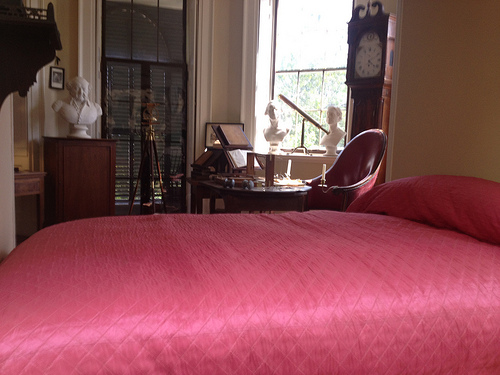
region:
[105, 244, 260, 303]
The blanket on the bed is red.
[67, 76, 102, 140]
The statue is white.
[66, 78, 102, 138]
The statue is a man.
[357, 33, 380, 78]
The clock face is white.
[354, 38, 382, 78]
The clock numbers are black.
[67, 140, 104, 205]
The stand is brown.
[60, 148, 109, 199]
The stand is made from wood.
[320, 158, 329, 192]
The candle is white.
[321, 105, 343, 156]
The statue is white.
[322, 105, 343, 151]
The statue is of a woman.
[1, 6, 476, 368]
Bedroom with furniture and busts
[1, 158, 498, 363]
Made red blanket and pillows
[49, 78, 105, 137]
Armless white plaster bust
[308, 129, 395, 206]
Red concave table chair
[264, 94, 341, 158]
Two white plaster busts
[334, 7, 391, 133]
Brown wooden grandfather clock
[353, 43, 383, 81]
Clock face reading 06:22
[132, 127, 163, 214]
Black and gold tripod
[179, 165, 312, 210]
Brown wooden reading table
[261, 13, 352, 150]
Sun drenched window frame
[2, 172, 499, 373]
hot pink quilted bedspread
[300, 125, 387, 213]
hot pink leather chair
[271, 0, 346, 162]
sun coming in through window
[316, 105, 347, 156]
statue of a man's head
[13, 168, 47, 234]
wooden nightstand with one drawer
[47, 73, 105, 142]
bust of a heavy man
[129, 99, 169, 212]
brown and gold telescope on tripod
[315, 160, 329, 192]
white candle in brass candle holder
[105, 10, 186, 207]
closed blinds on window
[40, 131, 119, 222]
dark stained wooden cabinet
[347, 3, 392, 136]
part of a large grandfather clock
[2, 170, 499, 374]
a large pink bed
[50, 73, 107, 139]
a white sculpture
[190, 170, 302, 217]
part of a brown table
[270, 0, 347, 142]
part of a window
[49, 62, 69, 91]
a small picture frame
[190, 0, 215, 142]
white wall trim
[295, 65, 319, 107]
green tree leaves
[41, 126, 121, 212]
part of a brown cabinet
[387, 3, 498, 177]
a yellow painted wall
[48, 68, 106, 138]
A small white bust of an old man's head and shoulders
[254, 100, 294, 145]
Statute of a person's upper torso bathed in light from the sun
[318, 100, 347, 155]
White bust of a person resting on a wooden still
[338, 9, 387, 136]
Tall brown wooden grandfather clock with a white face and black hands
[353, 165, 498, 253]
Red pillow at the head of a bed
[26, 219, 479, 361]
Red sheet with a square design covering a bed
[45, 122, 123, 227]
Dark wooden cabinet with a white bust on top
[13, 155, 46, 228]
Short wooden stand in front of a yellow wall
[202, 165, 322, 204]
Brown wooden table with light from the sun on it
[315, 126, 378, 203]
Dark red chair with sloping arm rests